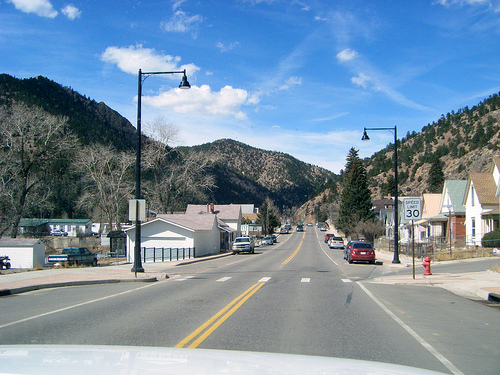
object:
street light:
[131, 68, 191, 273]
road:
[0, 226, 499, 374]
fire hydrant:
[421, 255, 432, 275]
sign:
[403, 198, 422, 221]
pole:
[412, 221, 415, 280]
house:
[124, 213, 221, 264]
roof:
[122, 215, 217, 232]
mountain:
[2, 74, 293, 227]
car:
[347, 241, 375, 264]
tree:
[426, 156, 446, 194]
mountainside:
[287, 90, 500, 225]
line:
[175, 280, 258, 347]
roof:
[17, 218, 91, 227]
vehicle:
[296, 223, 304, 232]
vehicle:
[232, 236, 256, 255]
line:
[300, 278, 310, 283]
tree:
[336, 146, 378, 239]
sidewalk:
[0, 226, 286, 297]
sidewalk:
[325, 218, 500, 305]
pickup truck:
[47, 247, 98, 267]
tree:
[474, 120, 487, 148]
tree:
[320, 193, 329, 206]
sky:
[1, 2, 497, 176]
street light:
[360, 125, 400, 263]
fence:
[137, 247, 196, 263]